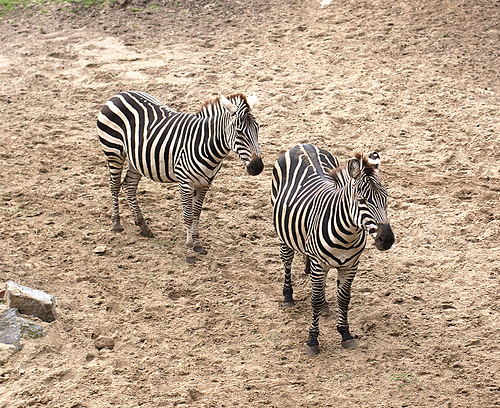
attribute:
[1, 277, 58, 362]
stone — big , white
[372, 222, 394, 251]
nose — is black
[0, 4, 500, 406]
field — is dirt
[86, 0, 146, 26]
patch — is small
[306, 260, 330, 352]
leg — black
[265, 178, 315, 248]
belly — fat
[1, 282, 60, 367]
rocks — large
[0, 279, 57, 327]
rock — small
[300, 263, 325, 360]
leg — black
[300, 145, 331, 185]
long stripe — black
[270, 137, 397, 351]
zebra — is black, is white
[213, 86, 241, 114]
ear — long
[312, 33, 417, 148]
grass — little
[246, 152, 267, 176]
nose — black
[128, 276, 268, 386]
sand — brown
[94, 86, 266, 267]
zebra — is black, is white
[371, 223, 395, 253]
nose — black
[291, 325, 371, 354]
feet — black